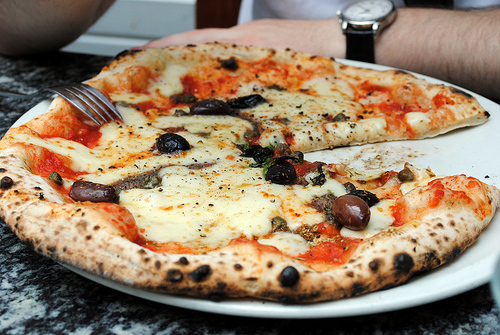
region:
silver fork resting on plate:
[14, 68, 124, 140]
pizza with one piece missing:
[8, 33, 498, 331]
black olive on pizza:
[329, 190, 370, 237]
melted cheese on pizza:
[157, 172, 237, 232]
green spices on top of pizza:
[184, 133, 335, 237]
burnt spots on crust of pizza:
[184, 258, 312, 290]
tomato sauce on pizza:
[25, 141, 80, 186]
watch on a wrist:
[329, 1, 401, 58]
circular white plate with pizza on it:
[334, 229, 474, 314]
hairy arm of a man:
[404, 15, 495, 54]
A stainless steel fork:
[12, 65, 122, 129]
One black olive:
[147, 132, 188, 154]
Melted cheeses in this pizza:
[136, 187, 266, 235]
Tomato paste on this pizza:
[18, 145, 79, 183]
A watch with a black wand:
[338, 0, 393, 64]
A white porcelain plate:
[423, 285, 470, 296]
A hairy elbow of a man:
[404, 3, 491, 72]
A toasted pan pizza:
[375, 235, 449, 270]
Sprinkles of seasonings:
[268, 106, 352, 129]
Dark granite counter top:
[10, 285, 97, 332]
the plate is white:
[458, 277, 461, 294]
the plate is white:
[411, 283, 430, 313]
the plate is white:
[429, 284, 442, 311]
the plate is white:
[443, 281, 450, 305]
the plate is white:
[424, 276, 433, 305]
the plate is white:
[419, 272, 426, 320]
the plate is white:
[424, 287, 430, 308]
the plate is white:
[393, 297, 405, 328]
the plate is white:
[407, 283, 418, 332]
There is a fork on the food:
[11, 65, 128, 152]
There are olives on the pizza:
[203, 182, 413, 267]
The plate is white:
[376, 107, 498, 310]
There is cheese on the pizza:
[160, 172, 301, 260]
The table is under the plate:
[5, 252, 61, 331]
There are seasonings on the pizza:
[136, 74, 328, 288]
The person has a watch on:
[326, 2, 405, 72]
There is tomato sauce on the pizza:
[259, 206, 368, 297]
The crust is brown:
[38, 196, 302, 284]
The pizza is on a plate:
[36, 66, 427, 327]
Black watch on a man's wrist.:
[325, 0, 406, 67]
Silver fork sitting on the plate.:
[0, 72, 128, 133]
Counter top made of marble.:
[3, 268, 55, 326]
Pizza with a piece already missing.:
[8, 40, 495, 266]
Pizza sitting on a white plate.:
[3, 37, 498, 292]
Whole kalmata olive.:
[327, 195, 374, 232]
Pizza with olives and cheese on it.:
[21, 37, 457, 282]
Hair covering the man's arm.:
[406, 5, 498, 63]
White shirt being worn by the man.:
[248, 0, 333, 15]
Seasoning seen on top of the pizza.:
[112, 162, 165, 194]